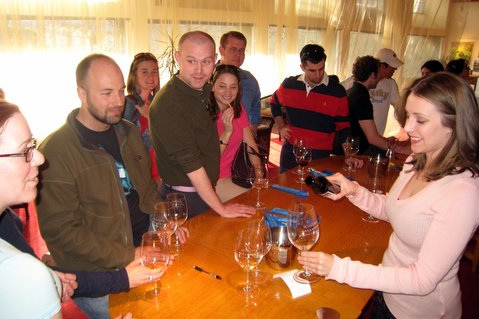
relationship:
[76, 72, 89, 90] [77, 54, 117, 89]
part of hair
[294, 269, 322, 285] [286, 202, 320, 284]
part of glass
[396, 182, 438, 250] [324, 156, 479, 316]
part of a blouse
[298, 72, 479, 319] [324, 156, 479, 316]
lady in blouse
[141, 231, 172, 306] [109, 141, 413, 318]
glass on table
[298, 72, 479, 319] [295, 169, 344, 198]
lady holding bottle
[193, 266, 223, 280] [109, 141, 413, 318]
pen on table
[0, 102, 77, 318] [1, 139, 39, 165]
person with glasses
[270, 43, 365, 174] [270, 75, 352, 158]
man in shirt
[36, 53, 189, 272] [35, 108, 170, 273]
man in jacket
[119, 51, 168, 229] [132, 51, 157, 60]
girl with sunglasses